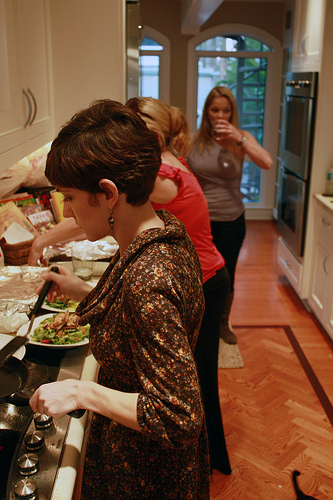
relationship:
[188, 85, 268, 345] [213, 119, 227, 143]
woman drinking from glass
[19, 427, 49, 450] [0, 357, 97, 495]
knob on stove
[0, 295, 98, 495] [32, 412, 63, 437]
stove has knob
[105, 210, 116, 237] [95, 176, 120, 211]
earring on ear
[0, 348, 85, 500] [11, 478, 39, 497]
stove has knob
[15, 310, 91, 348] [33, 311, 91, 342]
plate has food